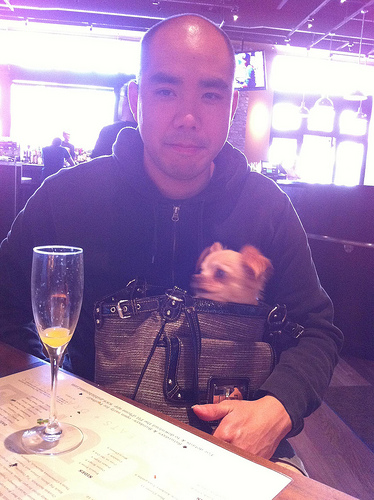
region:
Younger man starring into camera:
[125, 13, 240, 187]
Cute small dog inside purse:
[187, 239, 274, 306]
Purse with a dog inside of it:
[88, 279, 304, 446]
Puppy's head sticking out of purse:
[190, 240, 275, 312]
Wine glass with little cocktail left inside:
[20, 241, 89, 458]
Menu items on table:
[0, 359, 294, 498]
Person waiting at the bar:
[40, 138, 77, 186]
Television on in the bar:
[231, 49, 273, 98]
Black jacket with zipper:
[0, 125, 349, 439]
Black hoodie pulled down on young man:
[105, 125, 256, 212]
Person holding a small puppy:
[2, 17, 341, 477]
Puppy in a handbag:
[188, 240, 277, 313]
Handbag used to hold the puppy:
[95, 282, 277, 435]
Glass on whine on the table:
[18, 245, 85, 451]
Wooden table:
[0, 341, 362, 498]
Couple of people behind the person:
[40, 131, 83, 175]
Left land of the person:
[191, 393, 296, 461]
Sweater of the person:
[2, 129, 348, 434]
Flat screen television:
[233, 48, 265, 92]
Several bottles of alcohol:
[20, 146, 44, 165]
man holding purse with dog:
[52, 65, 343, 490]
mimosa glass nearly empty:
[22, 241, 96, 467]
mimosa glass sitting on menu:
[18, 239, 106, 461]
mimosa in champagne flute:
[24, 237, 96, 462]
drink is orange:
[36, 317, 79, 353]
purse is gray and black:
[95, 280, 293, 438]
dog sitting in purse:
[176, 249, 272, 323]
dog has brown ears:
[186, 237, 276, 309]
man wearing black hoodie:
[30, 127, 345, 438]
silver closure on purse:
[214, 377, 248, 407]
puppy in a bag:
[191, 237, 281, 304]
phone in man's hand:
[209, 367, 254, 408]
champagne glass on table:
[21, 229, 91, 465]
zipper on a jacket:
[164, 198, 186, 237]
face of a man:
[129, 12, 242, 185]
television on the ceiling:
[233, 41, 274, 97]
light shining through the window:
[19, 82, 101, 141]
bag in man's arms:
[101, 292, 289, 442]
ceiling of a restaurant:
[264, 1, 356, 53]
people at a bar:
[22, 126, 97, 187]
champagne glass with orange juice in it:
[21, 243, 83, 454]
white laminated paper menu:
[0, 363, 292, 498]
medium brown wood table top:
[0, 339, 360, 498]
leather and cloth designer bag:
[90, 272, 306, 434]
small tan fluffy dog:
[186, 241, 274, 304]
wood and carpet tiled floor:
[286, 351, 373, 497]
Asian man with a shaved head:
[0, 11, 346, 477]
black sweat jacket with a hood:
[0, 123, 344, 441]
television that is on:
[231, 48, 267, 93]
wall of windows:
[0, 17, 372, 185]